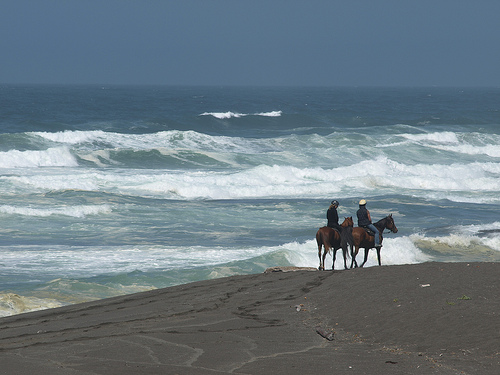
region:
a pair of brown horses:
[303, 192, 410, 284]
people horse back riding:
[295, 178, 412, 272]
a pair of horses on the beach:
[283, 185, 423, 297]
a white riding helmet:
[349, 194, 374, 208]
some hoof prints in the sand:
[242, 257, 322, 296]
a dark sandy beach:
[118, 266, 443, 358]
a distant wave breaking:
[195, 97, 305, 127]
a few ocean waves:
[32, 111, 279, 253]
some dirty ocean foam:
[0, 281, 66, 318]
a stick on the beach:
[308, 325, 343, 348]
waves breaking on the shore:
[401, 202, 495, 297]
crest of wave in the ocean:
[182, 97, 301, 137]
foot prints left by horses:
[206, 272, 348, 312]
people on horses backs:
[304, 190, 401, 257]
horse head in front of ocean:
[374, 207, 405, 242]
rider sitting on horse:
[352, 195, 376, 234]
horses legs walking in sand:
[301, 248, 394, 278]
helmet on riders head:
[344, 195, 376, 208]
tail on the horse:
[336, 230, 352, 263]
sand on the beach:
[321, 285, 470, 345]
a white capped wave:
[205, 97, 290, 129]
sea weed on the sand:
[83, 268, 323, 356]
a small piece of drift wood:
[285, 317, 355, 364]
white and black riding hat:
[348, 175, 381, 208]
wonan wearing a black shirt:
[325, 192, 345, 226]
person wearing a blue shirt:
[353, 201, 379, 231]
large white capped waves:
[245, 126, 455, 194]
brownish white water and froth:
[2, 275, 74, 322]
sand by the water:
[106, 249, 259, 374]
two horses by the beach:
[232, 166, 415, 320]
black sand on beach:
[9, 268, 496, 367]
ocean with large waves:
[20, 58, 482, 325]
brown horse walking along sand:
[313, 223, 349, 276]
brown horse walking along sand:
[346, 204, 410, 264]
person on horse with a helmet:
[355, 193, 388, 243]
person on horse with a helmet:
[321, 191, 338, 205]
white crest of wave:
[192, 108, 281, 122]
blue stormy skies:
[32, 18, 467, 100]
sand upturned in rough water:
[1, 257, 71, 321]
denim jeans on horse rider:
[368, 220, 388, 252]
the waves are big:
[107, 102, 327, 313]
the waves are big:
[74, 3, 272, 262]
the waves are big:
[61, 76, 269, 362]